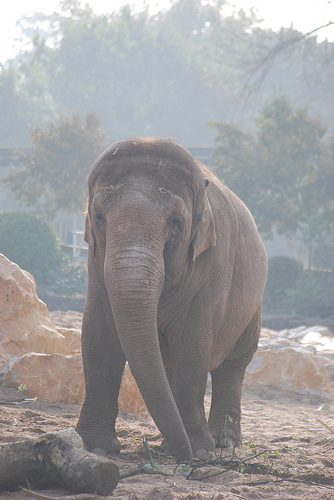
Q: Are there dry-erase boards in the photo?
A: No, there are no dry-erase boards.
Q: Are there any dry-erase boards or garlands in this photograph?
A: No, there are no dry-erase boards or garlands.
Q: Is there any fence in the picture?
A: No, there are no fences.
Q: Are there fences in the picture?
A: No, there are no fences.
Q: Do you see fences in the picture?
A: No, there are no fences.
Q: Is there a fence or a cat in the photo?
A: No, there are no fences or cats.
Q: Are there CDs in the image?
A: No, there are no cds.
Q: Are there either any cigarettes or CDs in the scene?
A: No, there are no CDs or cigarettes.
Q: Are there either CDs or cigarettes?
A: No, there are no CDs or cigarettes.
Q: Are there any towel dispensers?
A: No, there are no towel dispensers.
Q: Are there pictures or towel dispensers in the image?
A: No, there are no towel dispensers or pictures.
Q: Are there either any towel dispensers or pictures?
A: No, there are no towel dispensers or pictures.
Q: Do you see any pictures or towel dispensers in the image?
A: No, there are no towel dispensers or pictures.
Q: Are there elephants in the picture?
A: Yes, there is an elephant.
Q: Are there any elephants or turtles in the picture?
A: Yes, there is an elephant.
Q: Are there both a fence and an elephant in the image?
A: No, there is an elephant but no fences.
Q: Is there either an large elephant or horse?
A: Yes, there is a large elephant.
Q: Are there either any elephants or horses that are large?
A: Yes, the elephant is large.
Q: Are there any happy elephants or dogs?
A: Yes, there is a happy elephant.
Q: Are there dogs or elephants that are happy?
A: Yes, the elephant is happy.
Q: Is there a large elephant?
A: Yes, there is a large elephant.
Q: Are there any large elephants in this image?
A: Yes, there is a large elephant.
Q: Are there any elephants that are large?
A: Yes, there is an elephant that is large.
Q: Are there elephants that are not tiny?
A: Yes, there is a large elephant.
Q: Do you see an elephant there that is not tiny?
A: Yes, there is a large elephant.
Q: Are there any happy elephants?
A: Yes, there is a happy elephant.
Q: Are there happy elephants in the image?
A: Yes, there is a happy elephant.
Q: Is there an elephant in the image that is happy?
A: Yes, there is a happy elephant.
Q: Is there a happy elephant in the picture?
A: Yes, there is a happy elephant.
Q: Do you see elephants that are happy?
A: Yes, there is an elephant that is happy.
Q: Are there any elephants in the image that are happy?
A: Yes, there is an elephant that is happy.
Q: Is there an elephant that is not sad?
A: Yes, there is a happy elephant.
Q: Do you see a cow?
A: No, there are no cows.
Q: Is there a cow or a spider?
A: No, there are no cows or spiders.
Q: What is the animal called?
A: The animal is an elephant.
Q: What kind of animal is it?
A: The animal is an elephant.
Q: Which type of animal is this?
A: This is an elephant.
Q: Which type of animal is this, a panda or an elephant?
A: This is an elephant.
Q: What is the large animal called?
A: The animal is an elephant.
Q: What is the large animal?
A: The animal is an elephant.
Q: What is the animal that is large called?
A: The animal is an elephant.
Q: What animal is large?
A: The animal is an elephant.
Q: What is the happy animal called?
A: The animal is an elephant.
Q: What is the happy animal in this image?
A: The animal is an elephant.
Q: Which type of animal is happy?
A: The animal is an elephant.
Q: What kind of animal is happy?
A: The animal is an elephant.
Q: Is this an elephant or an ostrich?
A: This is an elephant.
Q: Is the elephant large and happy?
A: Yes, the elephant is large and happy.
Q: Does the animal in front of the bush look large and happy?
A: Yes, the elephant is large and happy.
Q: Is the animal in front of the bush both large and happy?
A: Yes, the elephant is large and happy.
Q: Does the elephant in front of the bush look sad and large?
A: No, the elephant is large but happy.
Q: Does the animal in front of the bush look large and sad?
A: No, the elephant is large but happy.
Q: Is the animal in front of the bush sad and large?
A: No, the elephant is large but happy.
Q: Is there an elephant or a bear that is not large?
A: No, there is an elephant but it is large.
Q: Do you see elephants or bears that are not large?
A: No, there is an elephant but it is large.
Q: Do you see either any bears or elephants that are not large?
A: No, there is an elephant but it is large.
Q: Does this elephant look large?
A: Yes, the elephant is large.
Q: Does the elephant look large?
A: Yes, the elephant is large.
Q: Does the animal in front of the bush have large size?
A: Yes, the elephant is large.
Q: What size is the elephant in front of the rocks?
A: The elephant is large.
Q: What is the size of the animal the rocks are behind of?
A: The elephant is large.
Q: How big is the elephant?
A: The elephant is large.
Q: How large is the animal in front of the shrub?
A: The elephant is large.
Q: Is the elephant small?
A: No, the elephant is large.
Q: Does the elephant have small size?
A: No, the elephant is large.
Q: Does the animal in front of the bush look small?
A: No, the elephant is large.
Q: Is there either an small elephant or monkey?
A: No, there is an elephant but it is large.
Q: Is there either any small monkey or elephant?
A: No, there is an elephant but it is large.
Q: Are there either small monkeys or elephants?
A: No, there is an elephant but it is large.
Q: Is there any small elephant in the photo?
A: No, there is an elephant but it is large.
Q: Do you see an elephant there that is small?
A: No, there is an elephant but it is large.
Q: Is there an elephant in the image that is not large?
A: No, there is an elephant but it is large.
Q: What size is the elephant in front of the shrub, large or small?
A: The elephant is large.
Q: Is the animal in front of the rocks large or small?
A: The elephant is large.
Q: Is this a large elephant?
A: Yes, this is a large elephant.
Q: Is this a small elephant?
A: No, this is a large elephant.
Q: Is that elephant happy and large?
A: Yes, the elephant is happy and large.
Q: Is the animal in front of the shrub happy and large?
A: Yes, the elephant is happy and large.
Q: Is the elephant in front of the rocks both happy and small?
A: No, the elephant is happy but large.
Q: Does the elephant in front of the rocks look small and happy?
A: No, the elephant is happy but large.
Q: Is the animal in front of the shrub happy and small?
A: No, the elephant is happy but large.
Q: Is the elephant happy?
A: Yes, the elephant is happy.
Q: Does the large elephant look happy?
A: Yes, the elephant is happy.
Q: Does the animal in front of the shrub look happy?
A: Yes, the elephant is happy.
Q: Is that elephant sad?
A: No, the elephant is happy.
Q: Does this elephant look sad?
A: No, the elephant is happy.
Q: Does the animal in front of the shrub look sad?
A: No, the elephant is happy.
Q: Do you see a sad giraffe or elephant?
A: No, there is an elephant but it is happy.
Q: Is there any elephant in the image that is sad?
A: No, there is an elephant but it is happy.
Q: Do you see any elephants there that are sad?
A: No, there is an elephant but it is happy.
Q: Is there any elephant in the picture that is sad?
A: No, there is an elephant but it is happy.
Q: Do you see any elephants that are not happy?
A: No, there is an elephant but it is happy.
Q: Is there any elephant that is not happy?
A: No, there is an elephant but it is happy.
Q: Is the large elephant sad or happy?
A: The elephant is happy.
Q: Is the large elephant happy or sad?
A: The elephant is happy.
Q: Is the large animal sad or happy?
A: The elephant is happy.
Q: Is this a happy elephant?
A: Yes, this is a happy elephant.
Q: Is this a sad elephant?
A: No, this is a happy elephant.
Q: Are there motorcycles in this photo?
A: No, there are no motorcycles.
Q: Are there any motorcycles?
A: No, there are no motorcycles.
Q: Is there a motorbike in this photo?
A: No, there are no motorcycles.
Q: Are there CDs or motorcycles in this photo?
A: No, there are no motorcycles or cds.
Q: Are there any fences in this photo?
A: No, there are no fences.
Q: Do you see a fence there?
A: No, there are no fences.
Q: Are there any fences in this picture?
A: No, there are no fences.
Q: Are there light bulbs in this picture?
A: No, there are no light bulbs.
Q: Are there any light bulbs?
A: No, there are no light bulbs.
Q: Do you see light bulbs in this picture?
A: No, there are no light bulbs.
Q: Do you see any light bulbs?
A: No, there are no light bulbs.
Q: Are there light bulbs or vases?
A: No, there are no light bulbs or vases.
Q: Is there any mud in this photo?
A: Yes, there is mud.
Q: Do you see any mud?
A: Yes, there is mud.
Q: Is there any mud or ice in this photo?
A: Yes, there is mud.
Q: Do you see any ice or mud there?
A: Yes, there is mud.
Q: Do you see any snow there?
A: No, there is no snow.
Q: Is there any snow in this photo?
A: No, there is no snow.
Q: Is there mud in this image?
A: Yes, there is mud.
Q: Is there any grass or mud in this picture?
A: Yes, there is mud.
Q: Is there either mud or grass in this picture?
A: Yes, there is mud.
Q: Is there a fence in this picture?
A: No, there are no fences.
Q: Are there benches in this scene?
A: No, there are no benches.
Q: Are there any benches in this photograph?
A: No, there are no benches.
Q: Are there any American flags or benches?
A: No, there are no benches or American flags.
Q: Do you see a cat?
A: No, there are no cats.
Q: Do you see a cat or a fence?
A: No, there are no cats or fences.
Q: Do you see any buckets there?
A: No, there are no buckets.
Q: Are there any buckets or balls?
A: No, there are no buckets or balls.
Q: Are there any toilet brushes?
A: No, there are no toilet brushes.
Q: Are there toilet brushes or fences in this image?
A: No, there are no toilet brushes or fences.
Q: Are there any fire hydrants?
A: No, there are no fire hydrants.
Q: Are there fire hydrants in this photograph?
A: No, there are no fire hydrants.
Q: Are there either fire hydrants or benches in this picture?
A: No, there are no fire hydrants or benches.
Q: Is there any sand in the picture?
A: Yes, there is sand.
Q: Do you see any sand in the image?
A: Yes, there is sand.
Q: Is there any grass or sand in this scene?
A: Yes, there is sand.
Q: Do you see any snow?
A: No, there is no snow.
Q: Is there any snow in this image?
A: No, there is no snow.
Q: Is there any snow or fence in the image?
A: No, there are no snow or fences.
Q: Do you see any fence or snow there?
A: No, there are no snow or fences.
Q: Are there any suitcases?
A: No, there are no suitcases.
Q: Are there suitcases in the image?
A: No, there are no suitcases.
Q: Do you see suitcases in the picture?
A: No, there are no suitcases.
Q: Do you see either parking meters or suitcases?
A: No, there are no suitcases or parking meters.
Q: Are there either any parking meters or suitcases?
A: No, there are no suitcases or parking meters.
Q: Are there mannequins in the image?
A: No, there are no mannequins.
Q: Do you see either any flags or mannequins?
A: No, there are no mannequins or flags.